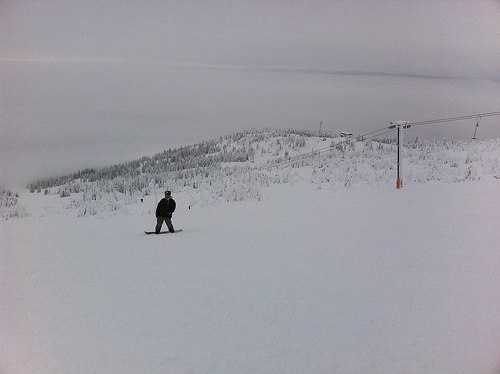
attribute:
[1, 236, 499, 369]
snow — white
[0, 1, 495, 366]
ground — white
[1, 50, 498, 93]
line — white, pale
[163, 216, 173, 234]
leg — apart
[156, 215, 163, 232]
leg — apart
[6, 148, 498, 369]
snow — white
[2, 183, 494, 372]
snow — white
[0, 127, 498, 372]
snow — white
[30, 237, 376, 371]
path — clear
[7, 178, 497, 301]
slope — curved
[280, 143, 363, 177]
stubble — upright